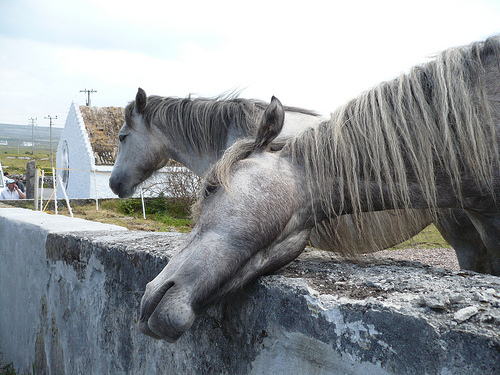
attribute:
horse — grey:
[108, 86, 199, 198]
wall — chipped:
[15, 221, 89, 363]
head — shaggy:
[142, 100, 323, 343]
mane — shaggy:
[354, 94, 422, 231]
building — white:
[57, 103, 109, 201]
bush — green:
[122, 201, 135, 214]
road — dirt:
[87, 210, 138, 222]